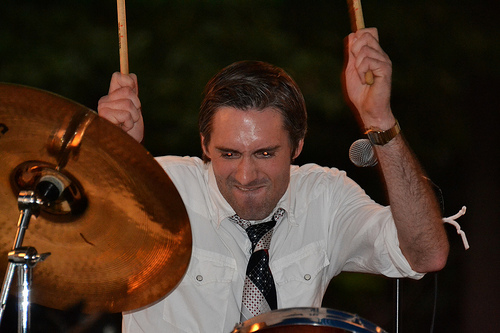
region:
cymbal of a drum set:
[0, 80, 190, 323]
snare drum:
[220, 295, 400, 325]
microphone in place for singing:
[340, 132, 380, 172]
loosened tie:
[220, 211, 292, 308]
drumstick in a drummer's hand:
[87, 15, 153, 145]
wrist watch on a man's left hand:
[355, 112, 411, 143]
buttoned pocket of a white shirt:
[280, 241, 340, 301]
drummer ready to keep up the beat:
[70, 20, 435, 325]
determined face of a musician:
[200, 50, 400, 230]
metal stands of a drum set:
[2, 172, 73, 328]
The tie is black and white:
[221, 211, 292, 324]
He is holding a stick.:
[339, 8, 404, 145]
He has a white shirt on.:
[113, 161, 421, 296]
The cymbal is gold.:
[5, 71, 200, 310]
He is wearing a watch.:
[367, 111, 415, 155]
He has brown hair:
[154, 56, 344, 255]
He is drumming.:
[45, 1, 498, 332]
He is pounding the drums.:
[47, 2, 419, 329]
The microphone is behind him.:
[339, 125, 395, 190]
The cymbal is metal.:
[3, 63, 199, 320]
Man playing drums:
[95, 25, 447, 327]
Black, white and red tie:
[236, 216, 278, 321]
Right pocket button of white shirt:
[190, 270, 205, 282]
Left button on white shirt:
[300, 267, 312, 282]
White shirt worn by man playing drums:
[120, 155, 422, 326]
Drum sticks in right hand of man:
[112, 11, 127, 72]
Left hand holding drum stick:
[350, 10, 366, 30]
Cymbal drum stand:
[0, 162, 53, 329]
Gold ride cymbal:
[1, 91, 197, 332]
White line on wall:
[389, 277, 401, 329]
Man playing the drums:
[93, 35, 445, 317]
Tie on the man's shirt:
[219, 215, 299, 325]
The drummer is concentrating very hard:
[190, 80, 330, 284]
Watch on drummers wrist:
[367, 122, 407, 151]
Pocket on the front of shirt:
[272, 240, 335, 300]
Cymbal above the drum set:
[2, 67, 196, 329]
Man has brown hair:
[199, 70, 311, 131]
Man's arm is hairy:
[361, 106, 464, 271]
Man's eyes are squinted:
[211, 132, 294, 174]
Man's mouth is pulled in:
[231, 183, 271, 196]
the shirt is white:
[167, 158, 347, 320]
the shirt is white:
[149, 190, 287, 305]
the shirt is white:
[150, 114, 292, 241]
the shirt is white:
[175, 114, 366, 266]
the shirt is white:
[237, 214, 335, 318]